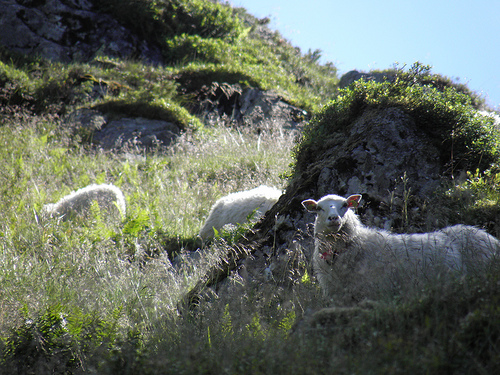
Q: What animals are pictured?
A: Sheep.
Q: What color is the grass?
A: Green.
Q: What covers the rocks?
A: Grass.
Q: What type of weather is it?
A: Sunny.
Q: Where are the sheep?
A: On a hillside.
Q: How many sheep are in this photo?
A: 3.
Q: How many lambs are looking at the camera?
A: 1.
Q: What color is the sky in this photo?
A: Blue.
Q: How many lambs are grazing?
A: 2.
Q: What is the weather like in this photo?
A: Sunny and nice.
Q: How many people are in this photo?
A: 0.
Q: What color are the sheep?
A: White.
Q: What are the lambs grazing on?
A: Grass.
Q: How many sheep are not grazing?
A: 1.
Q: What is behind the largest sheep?
A: A large rock.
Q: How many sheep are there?
A: Three.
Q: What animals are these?
A: Sheep.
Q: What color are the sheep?
A: White.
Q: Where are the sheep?
A: On a mountain.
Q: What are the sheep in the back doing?
A: Eating grass.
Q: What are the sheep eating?
A: Grass.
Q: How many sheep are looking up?
A: One.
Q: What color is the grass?
A: Tan and green.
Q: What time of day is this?
A: Daylight hours.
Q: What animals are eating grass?
A: Sheep.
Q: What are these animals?
A: Sheep.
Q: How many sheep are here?
A: Three.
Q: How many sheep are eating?
A: Two.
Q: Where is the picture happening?
A: The mountains.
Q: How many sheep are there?
A: 3.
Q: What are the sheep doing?
A: Eating.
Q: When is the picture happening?
A: Daytime.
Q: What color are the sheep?
A: White.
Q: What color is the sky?
A: Blue.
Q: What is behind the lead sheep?
A: A rock.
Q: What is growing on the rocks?
A: Vegetation.